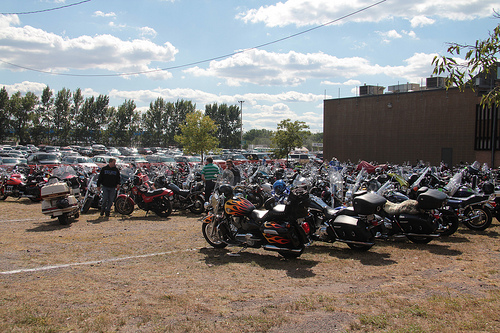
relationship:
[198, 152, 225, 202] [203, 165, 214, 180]
man wearing shirt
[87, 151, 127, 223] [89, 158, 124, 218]
man wearing sweater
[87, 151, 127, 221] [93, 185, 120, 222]
man wearing blue jeans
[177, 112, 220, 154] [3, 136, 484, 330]
tree in parking lot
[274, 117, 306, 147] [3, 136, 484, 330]
green tree in parking lot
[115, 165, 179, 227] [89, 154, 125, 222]
motorcycle next to man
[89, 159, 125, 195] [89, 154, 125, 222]
sweater on man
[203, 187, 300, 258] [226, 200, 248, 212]
motorcycle has flames